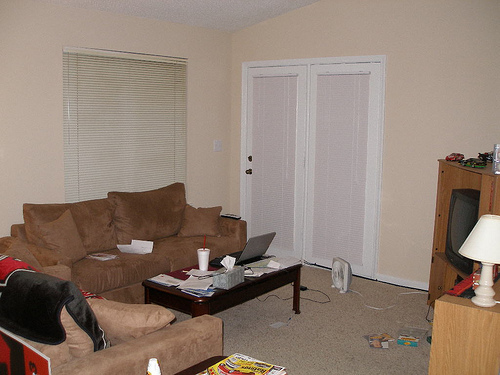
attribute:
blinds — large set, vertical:
[61, 44, 188, 201]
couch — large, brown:
[1, 175, 259, 301]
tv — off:
[442, 186, 479, 275]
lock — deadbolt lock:
[243, 152, 255, 164]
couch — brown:
[9, 179, 276, 316]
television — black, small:
[444, 184, 483, 280]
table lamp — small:
[456, 211, 498, 306]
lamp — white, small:
[449, 208, 497, 310]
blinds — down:
[45, 24, 210, 228]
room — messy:
[0, 4, 497, 369]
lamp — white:
[449, 212, 499, 317]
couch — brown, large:
[1, 149, 303, 338]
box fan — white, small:
[325, 254, 430, 313]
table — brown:
[137, 248, 304, 320]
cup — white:
[195, 247, 211, 270]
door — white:
[238, 64, 303, 263]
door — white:
[240, 55, 389, 283]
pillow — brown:
[178, 202, 222, 236]